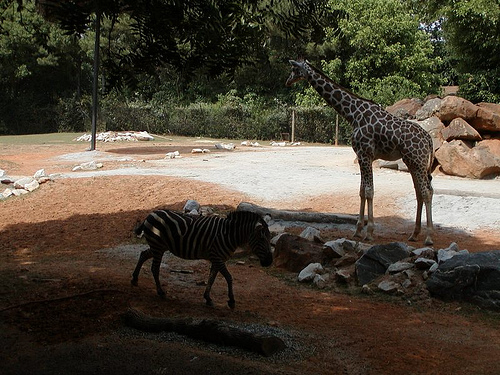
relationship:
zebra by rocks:
[130, 202, 277, 317] [299, 233, 484, 304]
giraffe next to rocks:
[283, 55, 435, 245] [285, 218, 481, 306]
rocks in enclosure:
[372, 93, 482, 184] [0, 64, 499, 373]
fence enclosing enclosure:
[2, 94, 353, 146] [0, 64, 499, 373]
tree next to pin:
[326, 10, 479, 115] [279, 91, 351, 153]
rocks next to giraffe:
[259, 207, 481, 327] [254, 36, 442, 260]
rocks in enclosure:
[372, 95, 500, 181] [372, 72, 474, 245]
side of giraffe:
[298, 59, 465, 249] [271, 40, 449, 258]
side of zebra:
[132, 209, 285, 319] [119, 194, 320, 331]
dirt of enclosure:
[7, 121, 484, 371] [2, 4, 480, 365]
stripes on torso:
[152, 215, 229, 260] [166, 215, 234, 261]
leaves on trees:
[1, 5, 480, 101] [6, 1, 484, 140]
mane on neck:
[229, 203, 269, 227] [216, 212, 254, 265]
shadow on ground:
[35, 195, 484, 363] [16, 121, 466, 372]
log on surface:
[131, 287, 301, 366] [52, 263, 483, 373]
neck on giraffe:
[310, 68, 376, 127] [271, 40, 449, 258]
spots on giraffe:
[307, 72, 321, 90] [270, 48, 461, 270]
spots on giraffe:
[312, 69, 328, 92] [271, 40, 449, 258]